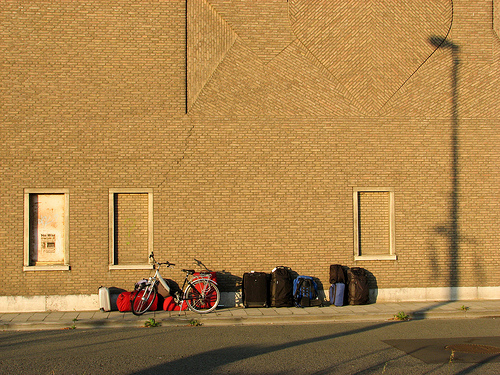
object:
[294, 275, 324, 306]
suitcases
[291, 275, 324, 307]
bags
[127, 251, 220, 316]
bike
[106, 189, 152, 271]
windows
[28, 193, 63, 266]
plywood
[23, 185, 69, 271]
window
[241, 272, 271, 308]
luggage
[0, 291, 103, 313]
base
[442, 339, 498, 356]
manhole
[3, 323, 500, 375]
road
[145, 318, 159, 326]
vegetation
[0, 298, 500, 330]
sidewalk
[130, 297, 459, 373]
shadow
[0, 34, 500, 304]
wall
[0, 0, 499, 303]
building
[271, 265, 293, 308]
luggage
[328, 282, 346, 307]
suitcases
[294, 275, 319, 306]
backpack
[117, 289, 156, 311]
bag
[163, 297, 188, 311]
gym bag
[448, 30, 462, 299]
pole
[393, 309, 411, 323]
weeds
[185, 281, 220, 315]
tire